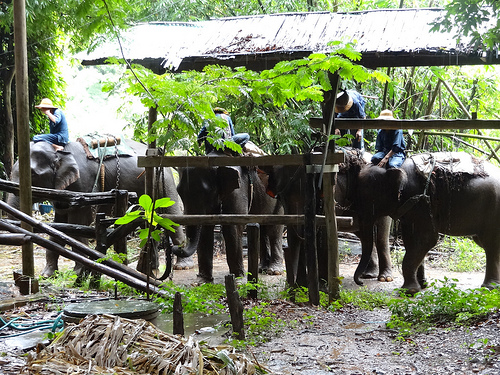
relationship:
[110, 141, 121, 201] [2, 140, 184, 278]
metal chain on elephant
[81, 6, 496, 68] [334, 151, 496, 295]
roof over elephant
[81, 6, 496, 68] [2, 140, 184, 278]
roof over elephant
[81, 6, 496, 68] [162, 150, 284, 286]
roof over elephant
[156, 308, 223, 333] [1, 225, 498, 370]
puddle on ground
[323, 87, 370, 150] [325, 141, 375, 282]
man on elephant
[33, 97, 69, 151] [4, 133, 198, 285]
man sitting on elephant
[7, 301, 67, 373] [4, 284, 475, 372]
hose on ground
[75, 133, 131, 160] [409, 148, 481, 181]
pack tied to pack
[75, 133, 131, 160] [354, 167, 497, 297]
pack tied to elephant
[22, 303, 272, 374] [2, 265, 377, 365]
haystack on ground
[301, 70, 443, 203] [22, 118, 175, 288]
workers by elephants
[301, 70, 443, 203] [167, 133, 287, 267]
workers by elephants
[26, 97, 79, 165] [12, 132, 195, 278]
man riding elephant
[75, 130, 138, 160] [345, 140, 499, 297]
saddle on elephant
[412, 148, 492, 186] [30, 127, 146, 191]
saddle on elephant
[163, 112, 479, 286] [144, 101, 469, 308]
elephants in pen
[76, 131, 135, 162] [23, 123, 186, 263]
pack on elephant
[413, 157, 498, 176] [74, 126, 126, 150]
blanket under package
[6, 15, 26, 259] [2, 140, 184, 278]
pole in front elephant